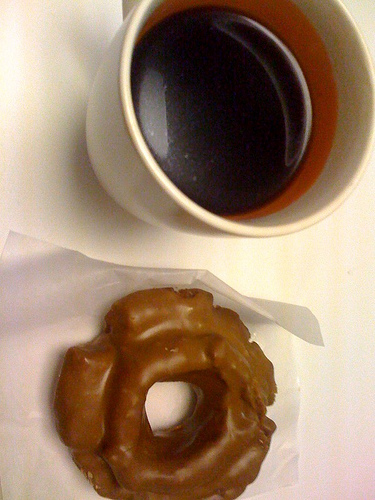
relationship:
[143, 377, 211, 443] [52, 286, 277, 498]
hole in donut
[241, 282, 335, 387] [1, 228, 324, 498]
corner of paper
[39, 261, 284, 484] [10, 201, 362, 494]
item on surface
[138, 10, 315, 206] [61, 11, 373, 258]
liquid in cup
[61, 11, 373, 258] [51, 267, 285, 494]
cup next to donut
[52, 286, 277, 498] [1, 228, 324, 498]
donut on paper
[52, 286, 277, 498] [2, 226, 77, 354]
donut on wax paper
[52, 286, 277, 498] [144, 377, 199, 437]
donut has hole